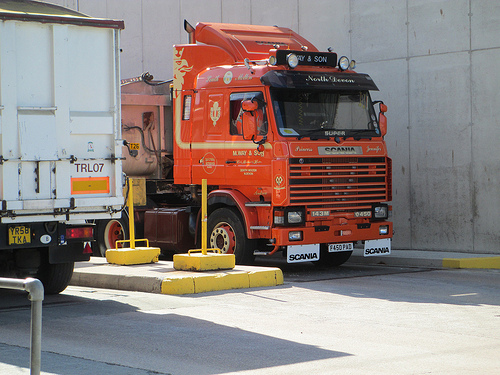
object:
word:
[323, 147, 354, 154]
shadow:
[0, 294, 354, 375]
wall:
[46, 0, 500, 257]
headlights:
[286, 211, 301, 223]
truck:
[120, 11, 398, 273]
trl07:
[70, 160, 107, 177]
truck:
[0, 0, 124, 296]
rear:
[0, 0, 126, 265]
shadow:
[251, 249, 500, 310]